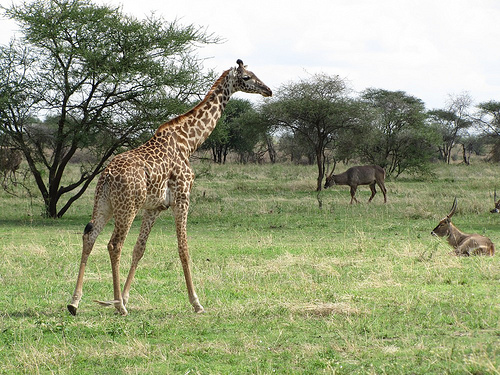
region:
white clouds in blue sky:
[256, 15, 301, 63]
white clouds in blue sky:
[289, 18, 326, 50]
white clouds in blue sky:
[341, 35, 351, 50]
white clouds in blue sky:
[360, 24, 382, 64]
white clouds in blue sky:
[390, 22, 415, 62]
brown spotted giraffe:
[82, 55, 277, 311]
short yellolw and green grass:
[238, 276, 303, 317]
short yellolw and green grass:
[322, 282, 357, 317]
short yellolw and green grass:
[382, 300, 423, 326]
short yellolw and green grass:
[150, 324, 198, 349]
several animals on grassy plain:
[45, 43, 498, 322]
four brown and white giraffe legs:
[57, 208, 207, 322]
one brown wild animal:
[316, 156, 393, 206]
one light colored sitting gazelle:
[426, 193, 497, 255]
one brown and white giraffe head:
[231, 58, 274, 98]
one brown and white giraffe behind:
[96, 162, 125, 203]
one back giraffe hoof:
[66, 298, 85, 318]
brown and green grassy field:
[216, 264, 411, 365]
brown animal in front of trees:
[275, 72, 430, 212]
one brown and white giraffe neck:
[165, 85, 234, 147]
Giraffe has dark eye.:
[234, 65, 256, 90]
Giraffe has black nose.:
[265, 81, 284, 116]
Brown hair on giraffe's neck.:
[143, 68, 228, 138]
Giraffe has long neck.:
[166, 68, 251, 164]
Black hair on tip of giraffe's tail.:
[80, 210, 99, 241]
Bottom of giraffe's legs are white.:
[57, 250, 225, 315]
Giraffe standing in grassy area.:
[41, 245, 237, 338]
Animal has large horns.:
[445, 197, 462, 221]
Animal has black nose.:
[423, 225, 445, 253]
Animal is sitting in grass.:
[416, 188, 491, 298]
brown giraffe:
[103, 55, 279, 303]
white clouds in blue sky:
[228, 2, 256, 43]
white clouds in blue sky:
[360, 10, 400, 56]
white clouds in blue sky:
[371, 3, 415, 65]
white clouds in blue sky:
[380, 14, 482, 42]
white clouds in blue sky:
[391, 34, 429, 78]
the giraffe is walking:
[10, 52, 285, 324]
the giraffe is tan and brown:
[97, 51, 241, 266]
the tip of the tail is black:
[50, 200, 118, 245]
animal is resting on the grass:
[420, 192, 487, 270]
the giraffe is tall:
[43, 51, 298, 288]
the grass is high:
[210, 231, 420, 358]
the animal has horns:
[437, 180, 464, 222]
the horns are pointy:
[428, 187, 460, 214]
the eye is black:
[232, 72, 255, 89]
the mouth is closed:
[255, 85, 273, 108]